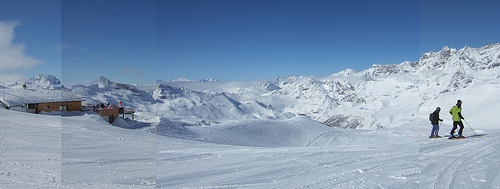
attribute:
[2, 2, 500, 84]
sky — blue, clear blue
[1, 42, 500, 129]
mountains — snowy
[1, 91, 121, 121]
building — yellow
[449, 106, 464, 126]
jacket — green, yellow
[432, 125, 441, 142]
pants — jeans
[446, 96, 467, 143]
person — skiing